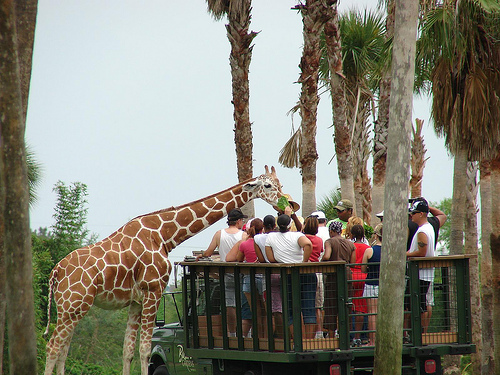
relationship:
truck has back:
[147, 255, 476, 373] [182, 262, 476, 374]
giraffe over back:
[43, 163, 293, 374] [182, 262, 476, 374]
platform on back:
[186, 335, 479, 360] [182, 262, 476, 374]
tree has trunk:
[2, 0, 39, 373] [6, 183, 39, 375]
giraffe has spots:
[43, 163, 293, 374] [69, 248, 164, 300]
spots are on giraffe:
[69, 248, 164, 300] [43, 163, 293, 374]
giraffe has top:
[43, 163, 293, 374] [247, 160, 289, 187]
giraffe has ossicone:
[43, 163, 293, 374] [263, 166, 270, 176]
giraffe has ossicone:
[43, 163, 293, 374] [270, 165, 279, 175]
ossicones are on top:
[260, 163, 280, 180] [247, 160, 289, 187]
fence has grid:
[297, 260, 470, 350] [301, 268, 459, 342]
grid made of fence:
[301, 268, 459, 342] [297, 260, 470, 350]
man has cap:
[408, 200, 439, 347] [408, 198, 432, 217]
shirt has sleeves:
[265, 231, 311, 264] [264, 232, 307, 247]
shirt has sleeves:
[410, 224, 440, 283] [417, 229, 431, 239]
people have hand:
[209, 198, 440, 351] [285, 206, 292, 217]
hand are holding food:
[285, 206, 292, 217] [277, 195, 292, 214]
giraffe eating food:
[43, 163, 293, 374] [277, 195, 292, 214]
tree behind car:
[308, 5, 396, 235] [147, 255, 476, 373]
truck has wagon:
[147, 255, 476, 373] [176, 255, 478, 363]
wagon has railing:
[176, 255, 478, 363] [173, 253, 478, 272]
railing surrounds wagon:
[173, 253, 478, 272] [176, 255, 478, 363]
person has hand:
[273, 194, 304, 233] [284, 205, 294, 217]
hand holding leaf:
[284, 205, 294, 217] [275, 196, 288, 211]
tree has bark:
[371, 2, 419, 374] [387, 159, 405, 271]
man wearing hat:
[408, 200, 439, 347] [408, 198, 432, 217]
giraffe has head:
[43, 163, 293, 374] [248, 163, 296, 217]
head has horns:
[248, 163, 296, 217] [260, 163, 280, 180]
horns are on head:
[260, 163, 280, 180] [248, 163, 296, 217]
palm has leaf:
[304, 7, 394, 92] [281, 100, 302, 170]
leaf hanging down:
[281, 100, 302, 170] [2, 368, 500, 375]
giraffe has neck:
[43, 163, 293, 374] [154, 179, 258, 255]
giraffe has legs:
[43, 163, 293, 374] [37, 290, 163, 373]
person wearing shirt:
[300, 213, 331, 344] [305, 235, 325, 263]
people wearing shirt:
[194, 208, 248, 340] [216, 226, 245, 261]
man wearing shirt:
[408, 200, 439, 347] [410, 224, 440, 283]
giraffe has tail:
[43, 163, 293, 374] [42, 265, 58, 337]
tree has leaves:
[51, 176, 93, 253] [59, 186, 86, 238]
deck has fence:
[176, 266, 477, 363] [297, 260, 470, 350]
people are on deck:
[209, 198, 440, 351] [176, 266, 477, 363]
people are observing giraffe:
[209, 198, 440, 351] [43, 163, 293, 374]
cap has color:
[408, 198, 432, 217] [412, 199, 430, 213]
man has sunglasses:
[408, 200, 439, 347] [411, 209, 423, 216]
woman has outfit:
[345, 240, 375, 345] [348, 242, 374, 312]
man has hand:
[273, 194, 304, 233] [284, 205, 294, 217]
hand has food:
[284, 205, 294, 217] [277, 195, 292, 214]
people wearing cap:
[194, 208, 248, 340] [226, 206, 250, 222]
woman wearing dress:
[345, 240, 375, 345] [348, 242, 374, 312]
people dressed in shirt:
[194, 208, 248, 340] [216, 226, 245, 261]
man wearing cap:
[329, 199, 373, 235] [333, 198, 355, 213]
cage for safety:
[181, 262, 462, 352] [185, 155, 476, 374]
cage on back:
[181, 262, 462, 352] [182, 262, 476, 374]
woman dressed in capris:
[265, 213, 322, 355] [281, 266, 320, 326]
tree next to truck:
[420, 2, 492, 253] [147, 255, 476, 373]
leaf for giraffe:
[275, 196, 288, 211] [43, 163, 293, 374]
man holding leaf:
[273, 194, 304, 233] [275, 196, 288, 211]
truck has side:
[147, 255, 476, 373] [145, 262, 292, 374]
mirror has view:
[150, 289, 180, 333] [157, 296, 164, 320]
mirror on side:
[150, 289, 180, 333] [145, 262, 292, 374]